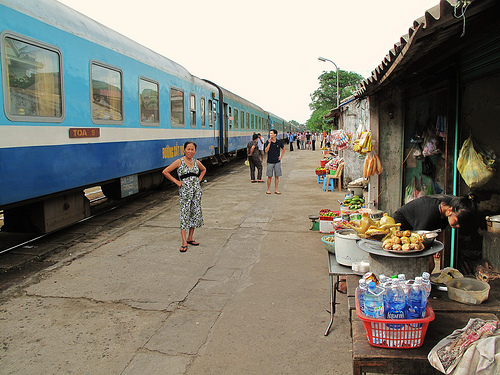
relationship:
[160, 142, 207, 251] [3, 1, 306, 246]
woman in front of train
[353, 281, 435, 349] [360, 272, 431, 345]
basket full of water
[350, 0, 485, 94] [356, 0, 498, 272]
roof of building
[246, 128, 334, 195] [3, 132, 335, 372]
people on platform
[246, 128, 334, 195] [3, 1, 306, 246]
people in front of train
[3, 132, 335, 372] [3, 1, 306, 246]
platform in front of train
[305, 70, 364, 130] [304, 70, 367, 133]
tree with leaves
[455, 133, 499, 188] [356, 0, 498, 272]
bag inside building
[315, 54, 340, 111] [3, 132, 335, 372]
light to illuminate platform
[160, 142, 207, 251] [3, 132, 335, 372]
woman standing on platform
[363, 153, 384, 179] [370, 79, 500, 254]
bananas on wall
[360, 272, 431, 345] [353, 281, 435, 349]
water in basket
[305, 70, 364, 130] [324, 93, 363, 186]
tree behind building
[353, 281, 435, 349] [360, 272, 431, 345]
basket with water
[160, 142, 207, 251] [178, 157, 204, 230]
woman wearing dress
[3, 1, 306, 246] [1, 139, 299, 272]
train on track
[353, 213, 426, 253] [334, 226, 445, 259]
food on plates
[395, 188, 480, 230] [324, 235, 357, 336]
woman bending over table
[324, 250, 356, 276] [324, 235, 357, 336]
edge of table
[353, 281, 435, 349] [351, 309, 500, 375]
basket on table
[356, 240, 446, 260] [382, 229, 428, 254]
plate of pastries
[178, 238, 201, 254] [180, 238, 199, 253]
flip flops on feet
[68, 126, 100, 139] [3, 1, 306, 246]
sign on train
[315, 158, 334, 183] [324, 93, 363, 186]
fruits in front of stall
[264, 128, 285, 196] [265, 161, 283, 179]
man wearing shorts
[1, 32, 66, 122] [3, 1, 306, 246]
window in train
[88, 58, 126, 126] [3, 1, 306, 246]
window in train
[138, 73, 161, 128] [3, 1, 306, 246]
window in train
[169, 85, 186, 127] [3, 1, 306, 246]
window in train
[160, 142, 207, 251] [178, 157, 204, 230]
woman with dress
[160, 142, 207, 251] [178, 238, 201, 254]
woman with flip flops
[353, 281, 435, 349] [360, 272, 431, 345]
basket with bottles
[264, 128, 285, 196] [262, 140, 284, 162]
man with shirt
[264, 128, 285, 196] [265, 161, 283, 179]
man with shorts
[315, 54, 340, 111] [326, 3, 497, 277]
light at end of buildings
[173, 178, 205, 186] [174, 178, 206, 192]
hands on hips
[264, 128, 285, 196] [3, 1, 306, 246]
man next to train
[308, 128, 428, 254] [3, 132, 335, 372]
food on platform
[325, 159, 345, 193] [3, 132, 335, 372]
chair on platform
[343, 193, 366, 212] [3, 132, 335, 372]
bananas on platform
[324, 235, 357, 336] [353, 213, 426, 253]
table with food